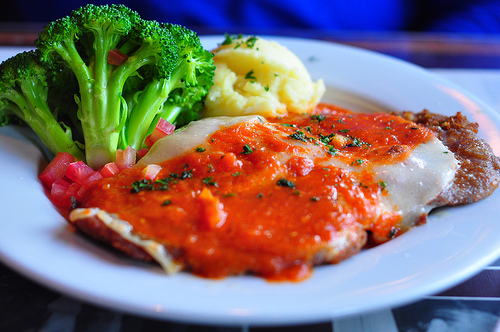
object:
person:
[136, 0, 500, 66]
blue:
[307, 0, 391, 35]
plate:
[0, 32, 500, 328]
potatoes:
[199, 37, 324, 116]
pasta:
[68, 102, 500, 281]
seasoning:
[131, 38, 388, 207]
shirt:
[155, 0, 500, 69]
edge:
[197, 21, 411, 64]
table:
[0, 69, 500, 332]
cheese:
[371, 137, 460, 224]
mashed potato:
[199, 37, 326, 117]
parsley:
[218, 34, 236, 45]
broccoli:
[0, 1, 216, 166]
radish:
[38, 151, 79, 186]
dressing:
[54, 117, 360, 249]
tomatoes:
[36, 145, 164, 203]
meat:
[59, 104, 496, 281]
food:
[0, 0, 500, 287]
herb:
[200, 175, 217, 187]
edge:
[294, 250, 499, 325]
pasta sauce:
[226, 200, 285, 245]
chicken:
[67, 104, 499, 282]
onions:
[147, 116, 177, 141]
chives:
[131, 180, 149, 190]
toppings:
[64, 112, 423, 212]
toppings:
[215, 30, 268, 54]